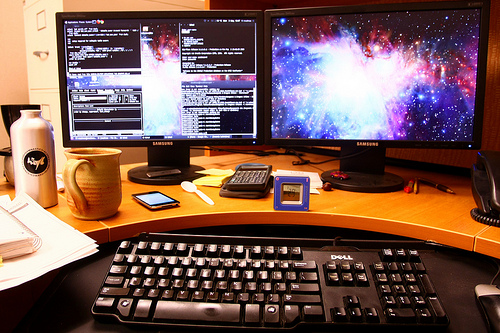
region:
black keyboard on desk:
[117, 238, 415, 325]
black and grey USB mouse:
[478, 286, 499, 331]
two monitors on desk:
[81, 0, 490, 160]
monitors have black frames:
[36, 21, 476, 163]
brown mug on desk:
[47, 117, 117, 212]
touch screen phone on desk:
[126, 193, 181, 218]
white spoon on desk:
[171, 177, 211, 217]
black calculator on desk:
[221, 152, 274, 204]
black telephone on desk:
[450, 160, 498, 227]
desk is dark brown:
[355, 196, 490, 249]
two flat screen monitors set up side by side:
[52, 6, 489, 192]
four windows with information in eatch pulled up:
[56, 15, 265, 147]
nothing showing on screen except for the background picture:
[270, 8, 478, 138]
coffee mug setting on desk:
[64, 147, 124, 219]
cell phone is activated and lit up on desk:
[129, 190, 179, 210]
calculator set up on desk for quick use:
[220, 158, 271, 198]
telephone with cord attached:
[471, 147, 497, 225]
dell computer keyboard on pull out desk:
[93, 230, 447, 330]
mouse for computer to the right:
[471, 280, 498, 331]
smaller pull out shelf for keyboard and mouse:
[76, 228, 498, 330]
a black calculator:
[218, 154, 283, 220]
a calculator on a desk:
[198, 147, 312, 230]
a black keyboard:
[101, 230, 388, 332]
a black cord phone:
[436, 140, 498, 212]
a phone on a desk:
[432, 121, 499, 223]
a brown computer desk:
[26, 116, 495, 283]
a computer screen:
[30, 26, 270, 183]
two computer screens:
[51, 38, 479, 209]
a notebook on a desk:
[3, 183, 57, 280]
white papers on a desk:
[2, 162, 142, 301]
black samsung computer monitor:
[267, 5, 484, 148]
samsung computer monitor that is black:
[61, 13, 263, 145]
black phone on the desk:
[470, 149, 498, 227]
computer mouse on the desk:
[474, 284, 498, 331]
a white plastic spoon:
[179, 177, 223, 209]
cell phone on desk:
[132, 186, 180, 222]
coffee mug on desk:
[63, 146, 132, 220]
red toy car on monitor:
[322, 168, 351, 185]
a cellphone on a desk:
[131, 187, 181, 212]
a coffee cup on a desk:
[63, 142, 124, 221]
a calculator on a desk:
[217, 158, 273, 201]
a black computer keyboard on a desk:
[93, 226, 452, 331]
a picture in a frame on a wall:
[34, 10, 49, 34]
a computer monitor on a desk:
[51, 8, 266, 188]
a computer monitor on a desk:
[260, 1, 488, 190]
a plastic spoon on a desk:
[178, 178, 217, 208]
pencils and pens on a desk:
[402, 168, 461, 202]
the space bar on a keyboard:
[153, 295, 245, 327]